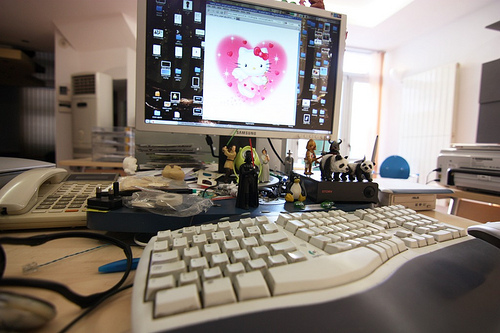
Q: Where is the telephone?
A: On the left.